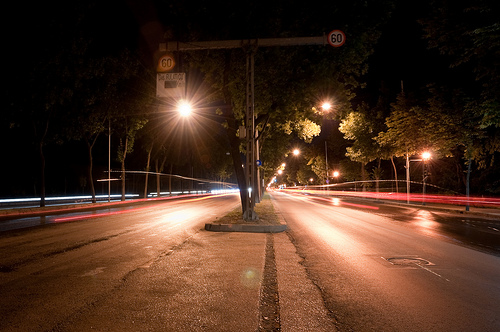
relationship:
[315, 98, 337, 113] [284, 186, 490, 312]
light above street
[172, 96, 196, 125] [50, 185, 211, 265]
light above street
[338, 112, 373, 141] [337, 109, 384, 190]
leaves on tree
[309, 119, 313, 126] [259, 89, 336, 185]
leaf on tree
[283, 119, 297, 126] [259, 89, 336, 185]
leaf on tree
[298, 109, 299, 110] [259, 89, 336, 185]
leaf on tree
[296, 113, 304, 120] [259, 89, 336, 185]
leaf on tree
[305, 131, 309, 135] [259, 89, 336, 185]
leaf on tree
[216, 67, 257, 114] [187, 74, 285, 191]
leaves on tree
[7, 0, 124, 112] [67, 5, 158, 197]
leaves on tree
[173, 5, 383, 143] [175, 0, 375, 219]
leaves on tree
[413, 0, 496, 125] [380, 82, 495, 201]
leaves on tree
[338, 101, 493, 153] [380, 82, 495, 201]
leaves on tree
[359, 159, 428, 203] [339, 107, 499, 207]
branches of trees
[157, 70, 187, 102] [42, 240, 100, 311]
sign above street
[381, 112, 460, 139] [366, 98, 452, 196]
leaves on tree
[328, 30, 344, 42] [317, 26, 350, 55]
number on sign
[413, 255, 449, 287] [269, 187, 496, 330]
line on street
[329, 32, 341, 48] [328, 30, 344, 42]
sign has numbers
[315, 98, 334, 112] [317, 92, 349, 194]
light on pole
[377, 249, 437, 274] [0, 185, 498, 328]
sewer in street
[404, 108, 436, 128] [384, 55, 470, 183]
leaves on tree